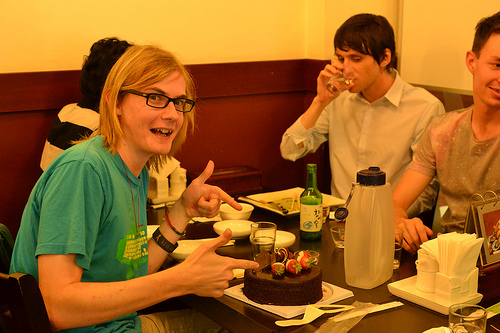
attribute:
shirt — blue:
[13, 135, 144, 331]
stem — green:
[269, 261, 284, 278]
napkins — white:
[417, 228, 485, 280]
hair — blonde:
[85, 31, 187, 169]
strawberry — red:
[268, 259, 288, 274]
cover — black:
[356, 165, 388, 185]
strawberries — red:
[272, 259, 286, 276]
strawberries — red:
[283, 255, 303, 274]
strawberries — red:
[296, 251, 315, 267]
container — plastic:
[344, 166, 396, 286]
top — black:
[354, 165, 386, 185]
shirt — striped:
[36, 96, 183, 206]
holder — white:
[431, 266, 484, 303]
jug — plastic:
[312, 151, 424, 288]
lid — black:
[341, 152, 397, 203]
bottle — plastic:
[348, 188, 375, 282]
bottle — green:
[302, 163, 324, 240]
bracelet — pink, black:
[158, 207, 188, 238]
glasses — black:
[118, 83, 199, 121]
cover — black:
[356, 161, 388, 190]